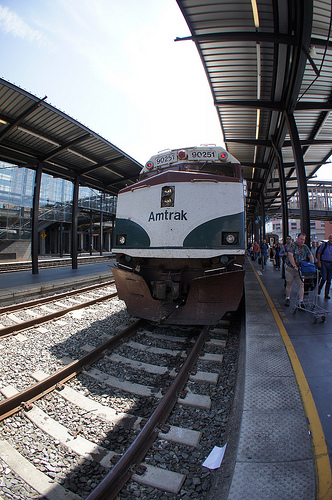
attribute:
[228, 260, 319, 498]
platform — train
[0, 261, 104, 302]
platform — train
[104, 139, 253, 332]
train — on, frront, stopping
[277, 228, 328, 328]
man — pushing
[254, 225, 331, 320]
passangers — carrying, disembarking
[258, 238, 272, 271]
person — waiting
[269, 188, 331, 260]
buildings — there\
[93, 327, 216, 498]
track — metallic, rusty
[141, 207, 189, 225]
word — written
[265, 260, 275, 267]
paper — white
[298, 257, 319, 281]
bag — blue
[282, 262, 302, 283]
pants — short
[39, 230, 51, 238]
sign — yellow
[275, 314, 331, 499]
line — yellow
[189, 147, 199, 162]
number — black